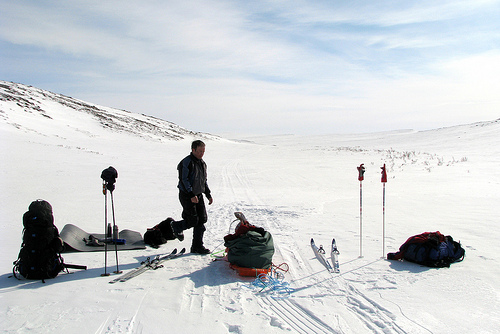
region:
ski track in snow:
[101, 293, 155, 331]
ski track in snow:
[164, 269, 208, 319]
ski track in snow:
[208, 279, 253, 323]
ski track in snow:
[262, 288, 319, 328]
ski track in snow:
[340, 291, 400, 332]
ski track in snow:
[274, 233, 308, 273]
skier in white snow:
[160, 147, 224, 267]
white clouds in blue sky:
[252, 4, 288, 36]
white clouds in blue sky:
[411, 25, 460, 52]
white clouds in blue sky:
[351, 32, 391, 57]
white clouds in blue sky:
[250, 21, 295, 51]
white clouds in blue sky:
[120, 49, 201, 85]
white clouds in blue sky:
[244, 29, 286, 76]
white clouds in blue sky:
[379, 62, 432, 81]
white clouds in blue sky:
[336, 49, 387, 115]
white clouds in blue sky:
[295, 38, 374, 89]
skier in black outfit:
[173, 141, 207, 241]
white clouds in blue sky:
[447, 51, 494, 108]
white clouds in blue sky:
[338, 21, 398, 85]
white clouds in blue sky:
[287, 66, 342, 119]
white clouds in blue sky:
[177, 42, 243, 84]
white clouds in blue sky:
[156, 19, 220, 64]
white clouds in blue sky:
[47, 4, 134, 59]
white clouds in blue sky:
[98, 36, 175, 72]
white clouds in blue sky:
[154, 47, 244, 122]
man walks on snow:
[147, 104, 223, 261]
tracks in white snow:
[217, 261, 342, 328]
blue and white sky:
[213, 3, 382, 124]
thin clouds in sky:
[213, 16, 318, 108]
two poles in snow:
[320, 129, 397, 258]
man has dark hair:
[190, 139, 230, 167]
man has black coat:
[175, 148, 204, 194]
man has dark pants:
[151, 192, 203, 263]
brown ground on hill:
[18, 84, 122, 124]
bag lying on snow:
[385, 209, 465, 269]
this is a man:
[132, 126, 226, 265]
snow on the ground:
[25, 77, 497, 329]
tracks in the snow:
[209, 176, 407, 324]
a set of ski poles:
[352, 152, 391, 263]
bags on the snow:
[11, 186, 482, 331]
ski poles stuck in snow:
[69, 145, 419, 282]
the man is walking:
[142, 126, 249, 271]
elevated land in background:
[3, 68, 265, 171]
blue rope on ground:
[228, 255, 299, 293]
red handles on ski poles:
[353, 159, 393, 183]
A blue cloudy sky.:
[0, 0, 498, 131]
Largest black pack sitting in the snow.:
[12, 198, 87, 280]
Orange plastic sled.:
[225, 247, 272, 280]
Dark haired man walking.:
[170, 140, 213, 255]